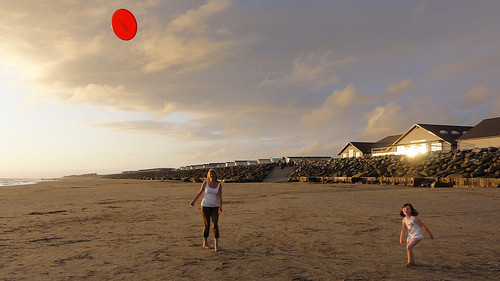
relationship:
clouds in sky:
[456, 84, 487, 111] [4, 2, 494, 175]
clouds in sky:
[456, 84, 487, 111] [1, 0, 500, 176]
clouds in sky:
[153, 8, 281, 136] [4, 2, 494, 175]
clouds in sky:
[295, 84, 369, 128] [4, 2, 494, 175]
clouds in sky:
[94, 74, 237, 132] [263, 30, 478, 99]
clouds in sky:
[456, 84, 487, 111] [325, 35, 423, 92]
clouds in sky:
[190, 45, 294, 137] [4, 2, 494, 175]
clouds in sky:
[25, 29, 102, 111] [1, 4, 493, 149]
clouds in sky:
[96, 120, 229, 142] [1, 4, 493, 149]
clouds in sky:
[380, 78, 411, 101] [1, 4, 493, 149]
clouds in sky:
[380, 78, 411, 101] [4, 2, 494, 175]